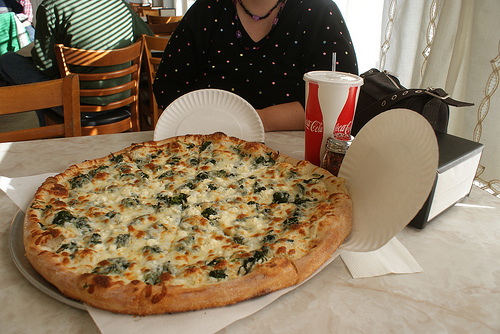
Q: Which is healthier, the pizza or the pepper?
A: The pepper is healthier than the pizza.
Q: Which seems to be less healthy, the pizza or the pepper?
A: The pizza is less healthy than the pepper.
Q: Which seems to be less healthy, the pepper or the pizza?
A: The pizza is less healthy than the pepper.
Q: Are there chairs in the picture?
A: Yes, there is a chair.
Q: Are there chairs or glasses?
A: Yes, there is a chair.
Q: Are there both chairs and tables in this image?
A: Yes, there are both a chair and a table.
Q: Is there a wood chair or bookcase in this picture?
A: Yes, there is a wood chair.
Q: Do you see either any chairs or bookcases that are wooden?
A: Yes, the chair is wooden.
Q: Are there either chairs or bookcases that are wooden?
A: Yes, the chair is wooden.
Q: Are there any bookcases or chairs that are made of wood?
A: Yes, the chair is made of wood.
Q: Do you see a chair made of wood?
A: Yes, there is a chair that is made of wood.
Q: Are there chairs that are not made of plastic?
A: Yes, there is a chair that is made of wood.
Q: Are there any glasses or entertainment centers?
A: No, there are no glasses or entertainment centers.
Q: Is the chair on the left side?
A: Yes, the chair is on the left of the image.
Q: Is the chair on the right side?
A: No, the chair is on the left of the image.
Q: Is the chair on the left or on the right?
A: The chair is on the left of the image.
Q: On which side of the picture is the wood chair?
A: The chair is on the left of the image.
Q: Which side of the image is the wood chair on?
A: The chair is on the left of the image.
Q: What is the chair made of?
A: The chair is made of wood.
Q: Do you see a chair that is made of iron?
A: No, there is a chair but it is made of wood.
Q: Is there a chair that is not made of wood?
A: No, there is a chair but it is made of wood.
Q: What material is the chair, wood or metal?
A: The chair is made of wood.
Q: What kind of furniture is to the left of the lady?
A: The piece of furniture is a chair.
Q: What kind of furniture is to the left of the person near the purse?
A: The piece of furniture is a chair.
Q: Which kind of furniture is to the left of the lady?
A: The piece of furniture is a chair.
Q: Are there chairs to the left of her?
A: Yes, there is a chair to the left of the lady.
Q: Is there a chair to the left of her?
A: Yes, there is a chair to the left of the lady.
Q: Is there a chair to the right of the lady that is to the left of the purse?
A: No, the chair is to the left of the lady.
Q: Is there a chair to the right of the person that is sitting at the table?
A: No, the chair is to the left of the lady.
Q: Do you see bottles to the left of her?
A: No, there is a chair to the left of the lady.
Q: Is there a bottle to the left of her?
A: No, there is a chair to the left of the lady.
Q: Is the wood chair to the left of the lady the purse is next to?
A: Yes, the chair is to the left of the lady.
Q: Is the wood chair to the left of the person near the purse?
A: Yes, the chair is to the left of the lady.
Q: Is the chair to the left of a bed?
A: No, the chair is to the left of the lady.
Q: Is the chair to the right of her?
A: No, the chair is to the left of the lady.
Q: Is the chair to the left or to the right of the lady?
A: The chair is to the left of the lady.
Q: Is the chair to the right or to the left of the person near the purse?
A: The chair is to the left of the lady.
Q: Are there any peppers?
A: Yes, there is a pepper.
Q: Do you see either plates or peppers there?
A: Yes, there is a pepper.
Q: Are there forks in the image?
A: No, there are no forks.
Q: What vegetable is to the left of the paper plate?
A: The vegetable is a pepper.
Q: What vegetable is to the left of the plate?
A: The vegetable is a pepper.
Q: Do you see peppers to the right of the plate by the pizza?
A: No, the pepper is to the left of the plate.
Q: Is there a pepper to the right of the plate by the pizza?
A: No, the pepper is to the left of the plate.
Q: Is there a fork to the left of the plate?
A: No, there is a pepper to the left of the plate.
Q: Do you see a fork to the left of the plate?
A: No, there is a pepper to the left of the plate.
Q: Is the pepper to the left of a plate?
A: Yes, the pepper is to the left of a plate.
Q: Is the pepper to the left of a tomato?
A: No, the pepper is to the left of a plate.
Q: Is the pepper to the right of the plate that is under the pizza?
A: No, the pepper is to the left of the plate.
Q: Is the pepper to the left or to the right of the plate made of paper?
A: The pepper is to the left of the plate.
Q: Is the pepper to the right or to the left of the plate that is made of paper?
A: The pepper is to the left of the plate.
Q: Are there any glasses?
A: No, there are no glasses.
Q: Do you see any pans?
A: Yes, there is a pan.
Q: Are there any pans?
A: Yes, there is a pan.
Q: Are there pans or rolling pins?
A: Yes, there is a pan.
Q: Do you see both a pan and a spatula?
A: No, there is a pan but no spatulas.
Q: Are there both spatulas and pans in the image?
A: No, there is a pan but no spatulas.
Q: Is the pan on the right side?
A: No, the pan is on the left of the image.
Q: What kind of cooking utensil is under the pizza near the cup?
A: The cooking utensil is a pan.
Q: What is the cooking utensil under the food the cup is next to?
A: The cooking utensil is a pan.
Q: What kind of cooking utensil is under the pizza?
A: The cooking utensil is a pan.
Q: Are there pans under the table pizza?
A: Yes, there is a pan under the pizza.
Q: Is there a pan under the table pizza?
A: Yes, there is a pan under the pizza.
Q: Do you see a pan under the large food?
A: Yes, there is a pan under the pizza.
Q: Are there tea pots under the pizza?
A: No, there is a pan under the pizza.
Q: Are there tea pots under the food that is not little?
A: No, there is a pan under the pizza.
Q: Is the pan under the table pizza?
A: Yes, the pan is under the pizza.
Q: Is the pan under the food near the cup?
A: Yes, the pan is under the pizza.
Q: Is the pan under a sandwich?
A: No, the pan is under the pizza.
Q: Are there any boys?
A: No, there are no boys.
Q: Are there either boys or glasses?
A: No, there are no boys or glasses.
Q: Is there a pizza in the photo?
A: Yes, there is a pizza.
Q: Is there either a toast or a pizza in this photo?
A: Yes, there is a pizza.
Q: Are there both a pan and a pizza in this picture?
A: Yes, there are both a pizza and a pan.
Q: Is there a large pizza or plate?
A: Yes, there is a large pizza.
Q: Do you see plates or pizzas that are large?
A: Yes, the pizza is large.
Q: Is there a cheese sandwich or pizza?
A: Yes, there is a cheese pizza.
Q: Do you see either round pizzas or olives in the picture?
A: Yes, there is a round pizza.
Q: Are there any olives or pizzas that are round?
A: Yes, the pizza is round.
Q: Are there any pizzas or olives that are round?
A: Yes, the pizza is round.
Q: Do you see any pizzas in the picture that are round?
A: Yes, there is a round pizza.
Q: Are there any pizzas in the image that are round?
A: Yes, there is a pizza that is round.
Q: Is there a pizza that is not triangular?
A: Yes, there is a round pizza.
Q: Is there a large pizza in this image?
A: Yes, there is a large pizza.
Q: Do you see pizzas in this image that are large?
A: Yes, there is a pizza that is large.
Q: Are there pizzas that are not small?
A: Yes, there is a large pizza.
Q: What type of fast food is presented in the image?
A: The fast food is a pizza.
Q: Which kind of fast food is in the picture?
A: The fast food is a pizza.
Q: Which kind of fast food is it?
A: The food is a pizza.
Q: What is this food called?
A: This is a pizza.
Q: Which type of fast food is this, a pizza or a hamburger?
A: This is a pizza.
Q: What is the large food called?
A: The food is a pizza.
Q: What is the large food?
A: The food is a pizza.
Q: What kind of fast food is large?
A: The fast food is a pizza.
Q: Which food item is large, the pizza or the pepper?
A: The pizza is large.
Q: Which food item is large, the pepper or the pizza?
A: The pizza is large.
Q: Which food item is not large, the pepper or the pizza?
A: The pepper is not large.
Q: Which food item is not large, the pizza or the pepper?
A: The pepper is not large.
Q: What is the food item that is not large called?
A: The food item is a pepper.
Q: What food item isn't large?
A: The food item is a pepper.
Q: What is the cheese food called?
A: The food is a pizza.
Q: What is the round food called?
A: The food is a pizza.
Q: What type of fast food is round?
A: The fast food is a pizza.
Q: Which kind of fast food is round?
A: The fast food is a pizza.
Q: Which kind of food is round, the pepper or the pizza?
A: The pizza is round.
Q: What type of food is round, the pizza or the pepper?
A: The pizza is round.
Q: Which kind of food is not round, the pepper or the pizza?
A: The pepper is not round.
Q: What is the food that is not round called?
A: The food is a pepper.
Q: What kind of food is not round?
A: The food is a pepper.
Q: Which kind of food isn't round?
A: The food is a pepper.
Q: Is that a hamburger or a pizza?
A: That is a pizza.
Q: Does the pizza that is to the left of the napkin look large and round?
A: Yes, the pizza is large and round.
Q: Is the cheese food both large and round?
A: Yes, the pizza is large and round.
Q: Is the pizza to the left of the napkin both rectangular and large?
A: No, the pizza is large but round.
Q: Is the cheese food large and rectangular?
A: No, the pizza is large but round.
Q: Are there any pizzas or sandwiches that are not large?
A: No, there is a pizza but it is large.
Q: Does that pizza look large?
A: Yes, the pizza is large.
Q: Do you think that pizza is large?
A: Yes, the pizza is large.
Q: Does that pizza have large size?
A: Yes, the pizza is large.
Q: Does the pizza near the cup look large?
A: Yes, the pizza is large.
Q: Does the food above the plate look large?
A: Yes, the pizza is large.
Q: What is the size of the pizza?
A: The pizza is large.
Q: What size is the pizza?
A: The pizza is large.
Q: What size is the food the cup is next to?
A: The pizza is large.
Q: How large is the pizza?
A: The pizza is large.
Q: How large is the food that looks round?
A: The pizza is large.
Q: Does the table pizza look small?
A: No, the pizza is large.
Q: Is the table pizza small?
A: No, the pizza is large.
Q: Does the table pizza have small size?
A: No, the pizza is large.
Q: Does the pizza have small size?
A: No, the pizza is large.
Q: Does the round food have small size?
A: No, the pizza is large.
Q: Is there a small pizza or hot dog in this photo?
A: No, there is a pizza but it is large.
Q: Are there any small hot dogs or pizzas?
A: No, there is a pizza but it is large.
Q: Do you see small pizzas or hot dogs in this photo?
A: No, there is a pizza but it is large.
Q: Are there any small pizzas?
A: No, there is a pizza but it is large.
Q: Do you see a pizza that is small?
A: No, there is a pizza but it is large.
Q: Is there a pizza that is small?
A: No, there is a pizza but it is large.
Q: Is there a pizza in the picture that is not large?
A: No, there is a pizza but it is large.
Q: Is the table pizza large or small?
A: The pizza is large.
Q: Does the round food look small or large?
A: The pizza is large.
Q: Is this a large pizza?
A: Yes, this is a large pizza.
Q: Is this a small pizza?
A: No, this is a large pizza.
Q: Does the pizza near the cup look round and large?
A: Yes, the pizza is round and large.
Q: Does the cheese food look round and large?
A: Yes, the pizza is round and large.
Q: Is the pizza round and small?
A: No, the pizza is round but large.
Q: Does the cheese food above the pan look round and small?
A: No, the pizza is round but large.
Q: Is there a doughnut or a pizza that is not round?
A: No, there is a pizza but it is round.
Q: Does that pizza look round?
A: Yes, the pizza is round.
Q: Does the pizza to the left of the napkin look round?
A: Yes, the pizza is round.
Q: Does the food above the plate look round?
A: Yes, the pizza is round.